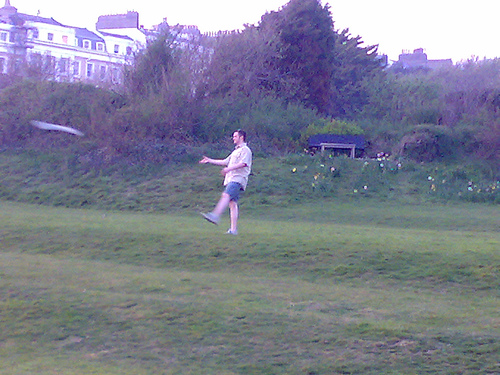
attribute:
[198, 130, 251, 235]
man — standing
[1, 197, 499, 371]
field — grass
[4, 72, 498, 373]
grass — green, short, dark, patchy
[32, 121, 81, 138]
object — flying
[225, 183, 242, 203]
shorts — blue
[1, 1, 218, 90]
building — white, tall, brick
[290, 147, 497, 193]
flowers — colorful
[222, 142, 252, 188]
shirt — light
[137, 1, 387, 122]
trees — thick, tall, fall colored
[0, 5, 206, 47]
roof — red, dark, brick